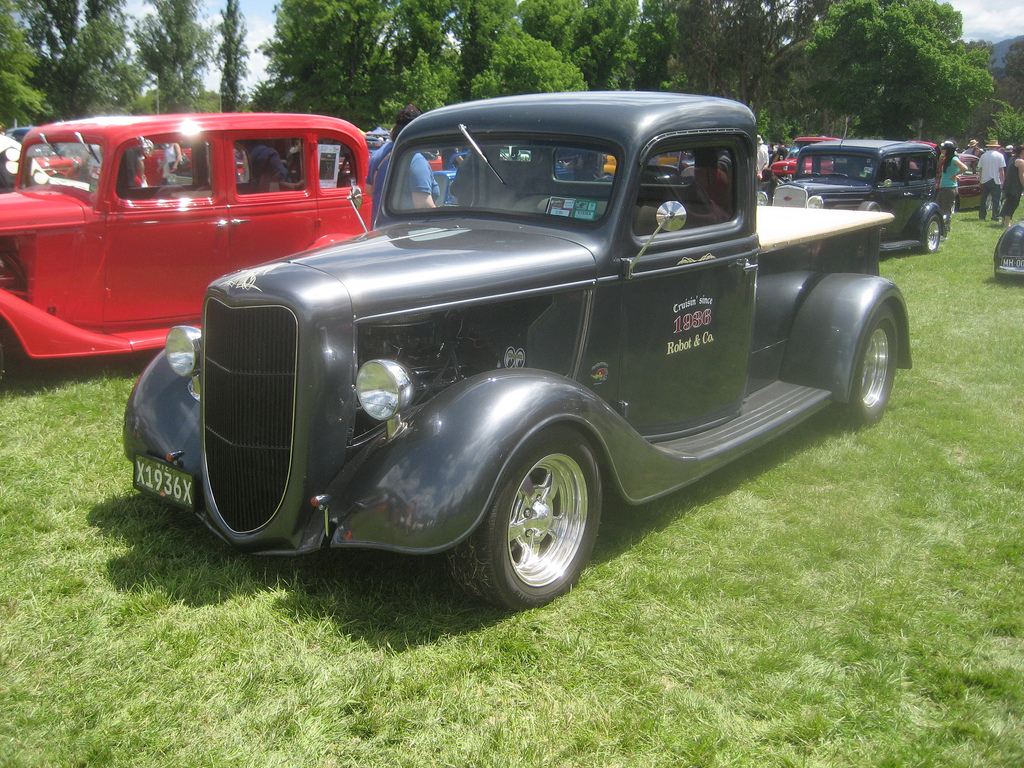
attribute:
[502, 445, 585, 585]
rim — tire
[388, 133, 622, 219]
glass — clean, clear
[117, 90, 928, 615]
truck — black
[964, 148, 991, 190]
shirt — white